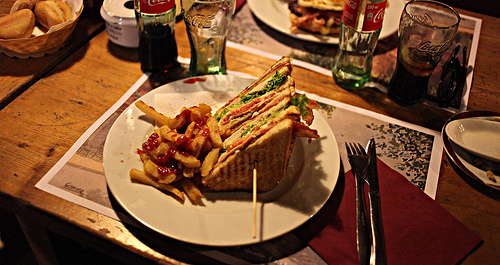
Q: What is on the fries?
A: Ketchup.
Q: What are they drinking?
A: Coca-Cola.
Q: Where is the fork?
A: Right of the plate.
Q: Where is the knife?
A: Right of the fork.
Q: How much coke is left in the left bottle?
A: Half.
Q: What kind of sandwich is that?
A: Club.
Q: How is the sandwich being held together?
A: Long toothpick.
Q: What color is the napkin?
A: Red.